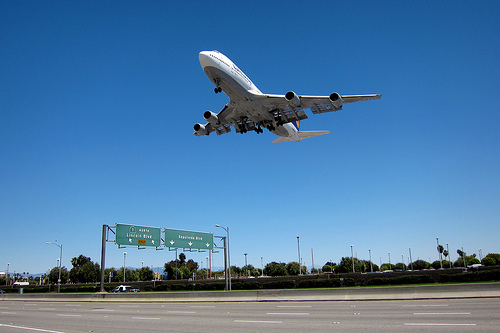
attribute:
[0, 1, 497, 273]
sky — clear, blue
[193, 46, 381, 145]
plane — taking off, white, small, flying, big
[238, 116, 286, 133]
wheels — down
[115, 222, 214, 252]
signs — green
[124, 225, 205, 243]
lettering — white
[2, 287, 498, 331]
street — clear, gray, paved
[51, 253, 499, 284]
bushes — green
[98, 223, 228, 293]
poles — gray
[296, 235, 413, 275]
poles — white